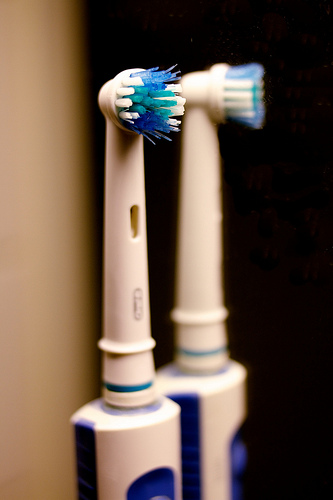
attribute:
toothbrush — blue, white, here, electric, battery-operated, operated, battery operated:
[54, 53, 191, 499]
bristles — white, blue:
[108, 71, 198, 138]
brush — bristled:
[90, 35, 178, 390]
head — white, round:
[63, 68, 197, 162]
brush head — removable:
[183, 67, 321, 384]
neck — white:
[49, 150, 156, 398]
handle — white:
[180, 126, 230, 356]